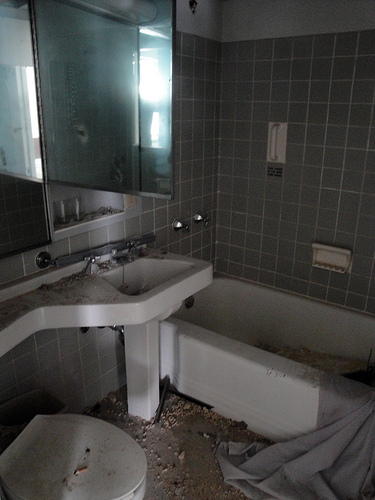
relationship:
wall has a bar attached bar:
[213, 29, 373, 318] [265, 122, 280, 162]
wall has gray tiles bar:
[213, 29, 373, 318] [265, 122, 280, 162]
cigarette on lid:
[72, 462, 88, 477] [6, 406, 150, 494]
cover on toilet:
[2, 417, 145, 498] [0, 412, 145, 499]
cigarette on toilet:
[74, 466, 88, 476] [14, 397, 145, 498]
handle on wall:
[173, 217, 192, 234] [3, 0, 214, 455]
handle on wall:
[192, 211, 213, 227] [3, 0, 214, 455]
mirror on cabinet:
[2, 2, 179, 202] [28, 0, 183, 244]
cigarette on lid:
[74, 466, 88, 476] [8, 410, 149, 498]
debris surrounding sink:
[107, 380, 247, 444] [78, 239, 215, 330]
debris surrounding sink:
[39, 259, 96, 304] [78, 239, 215, 330]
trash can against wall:
[17, 386, 80, 435] [3, 0, 214, 455]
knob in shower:
[192, 210, 213, 226] [152, 1, 374, 399]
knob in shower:
[172, 217, 192, 232] [152, 1, 374, 399]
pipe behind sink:
[114, 325, 125, 338] [78, 248, 212, 422]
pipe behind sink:
[78, 324, 95, 338] [78, 248, 212, 422]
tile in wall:
[310, 56, 333, 83] [213, 29, 373, 318]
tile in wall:
[305, 101, 328, 125] [213, 29, 373, 318]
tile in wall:
[300, 144, 324, 167] [213, 29, 373, 318]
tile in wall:
[250, 81, 272, 102] [213, 29, 373, 318]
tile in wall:
[260, 197, 283, 219] [213, 29, 373, 318]